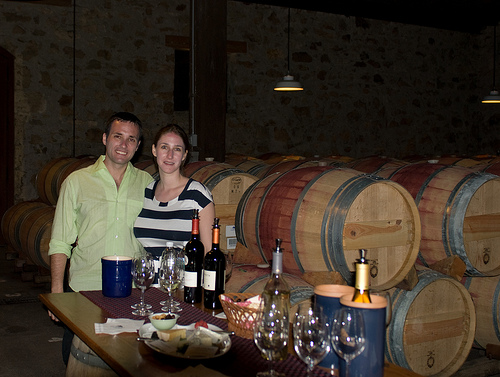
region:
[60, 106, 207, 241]
the man beside the woman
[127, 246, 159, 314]
glass on the table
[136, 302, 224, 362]
food on the tray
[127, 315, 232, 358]
the tray on the table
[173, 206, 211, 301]
the bottle on the table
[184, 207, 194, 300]
the bottle is blue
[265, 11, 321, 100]
the light hanging from the ceiling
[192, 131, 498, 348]
barrels beside the woman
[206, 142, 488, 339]
the barrels are wooden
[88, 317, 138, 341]
napkins on the table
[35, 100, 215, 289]
Happy couple at a wine tasting.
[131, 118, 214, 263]
Woman wearing a black and white shirt.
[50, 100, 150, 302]
Man in a button down dress shirt.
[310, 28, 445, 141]
Stone wall behind the kegs.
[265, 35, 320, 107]
Light hanging from the ceiling.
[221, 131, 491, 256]
Many many kegs filled with wine.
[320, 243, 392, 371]
Bottle of white wine chilling.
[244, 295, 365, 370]
Row of clear wine glasses.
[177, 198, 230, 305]
Two wines have been open and tasted.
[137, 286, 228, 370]
Plate of dip and chips.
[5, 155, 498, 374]
a bunch of wooden barrels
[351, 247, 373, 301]
a bottle of wine in a blue pot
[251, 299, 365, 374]
empty glasses of wine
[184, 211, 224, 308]
tow bottles of red wine on a table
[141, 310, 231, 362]
a white plate with cheeses and a white bowl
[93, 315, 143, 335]
papers on a table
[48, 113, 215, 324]
a man standing close to a woman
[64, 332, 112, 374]
a wooden barrel underneath a table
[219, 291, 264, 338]
a wicker basket with a red and white napkin in it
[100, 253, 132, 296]
a blue pot on a table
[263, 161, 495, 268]
Barrels of wine stacked together.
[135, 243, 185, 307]
Wine glasses on the table.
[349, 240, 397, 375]
A bottle of wine in the chiller.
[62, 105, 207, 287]
Two people standing by the table.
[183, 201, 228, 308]
Two bottles of wine on the table.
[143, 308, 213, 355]
Cheese and fruit on a plate.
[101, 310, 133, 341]
White napkins on the table.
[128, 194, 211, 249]
The shirt has black and white stripes.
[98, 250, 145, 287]
A blue cup on the table.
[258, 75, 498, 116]
Lights hanging from the ceiling.